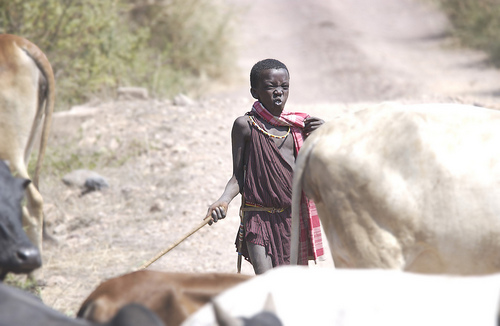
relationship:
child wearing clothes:
[205, 55, 326, 271] [242, 115, 317, 261]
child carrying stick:
[205, 55, 326, 271] [133, 217, 214, 274]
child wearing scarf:
[205, 55, 326, 271] [253, 102, 327, 256]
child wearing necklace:
[205, 55, 326, 271] [246, 112, 295, 141]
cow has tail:
[296, 101, 499, 280] [282, 127, 323, 264]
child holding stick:
[205, 55, 326, 271] [133, 217, 214, 274]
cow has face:
[0, 160, 89, 324] [0, 162, 44, 277]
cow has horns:
[116, 297, 286, 326] [208, 291, 289, 324]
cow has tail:
[0, 33, 54, 179] [20, 35, 51, 186]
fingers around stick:
[208, 202, 225, 222] [133, 217, 214, 274]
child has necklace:
[205, 55, 326, 271] [246, 112, 295, 141]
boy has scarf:
[205, 55, 326, 271] [253, 102, 327, 256]